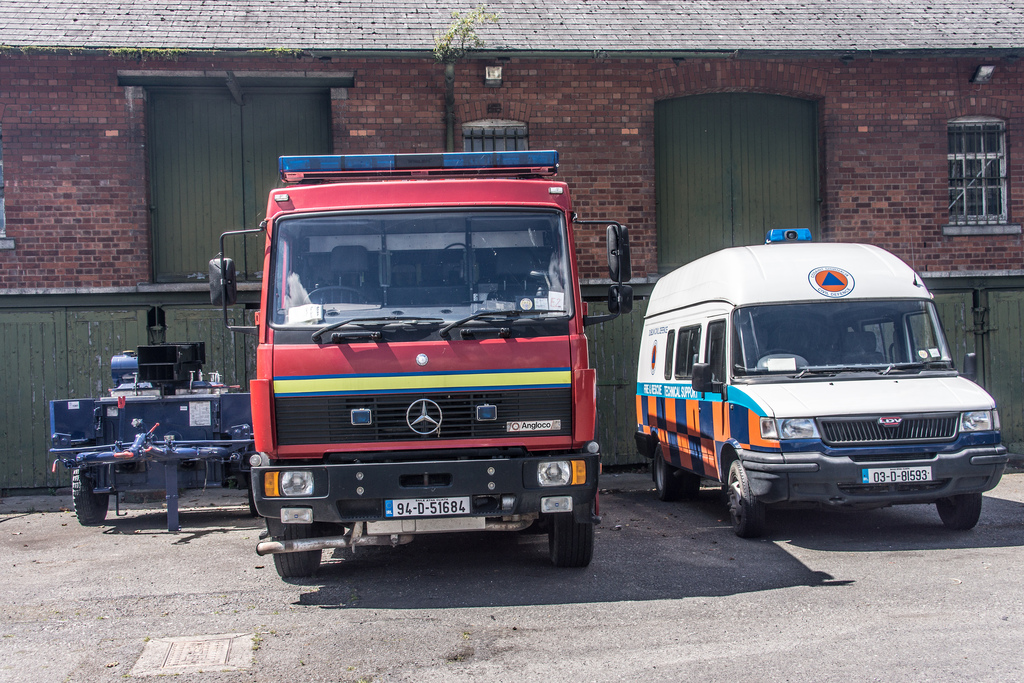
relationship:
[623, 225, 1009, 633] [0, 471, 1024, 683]
car on pavement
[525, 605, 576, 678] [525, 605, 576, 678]
pavement on road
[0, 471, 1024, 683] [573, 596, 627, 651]
pavement on road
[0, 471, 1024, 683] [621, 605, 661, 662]
pavement on road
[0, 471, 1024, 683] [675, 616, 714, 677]
pavement on road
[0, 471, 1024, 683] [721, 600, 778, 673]
pavement on road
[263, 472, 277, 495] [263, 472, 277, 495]
light on a vehicle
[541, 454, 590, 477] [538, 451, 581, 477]
light on a vehicle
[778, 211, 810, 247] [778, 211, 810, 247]
light on a vehicle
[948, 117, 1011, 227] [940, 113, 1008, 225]
bars covered in bars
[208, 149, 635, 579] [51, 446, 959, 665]
bus on road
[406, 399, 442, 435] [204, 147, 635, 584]
brand on bus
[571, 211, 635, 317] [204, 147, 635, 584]
mirror on bus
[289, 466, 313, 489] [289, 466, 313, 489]
light on vehicle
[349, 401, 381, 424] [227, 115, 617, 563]
light on vehicle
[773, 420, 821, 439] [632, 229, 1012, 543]
light on car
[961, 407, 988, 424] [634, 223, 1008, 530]
light on vehicle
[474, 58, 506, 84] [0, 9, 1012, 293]
light mounted on wall